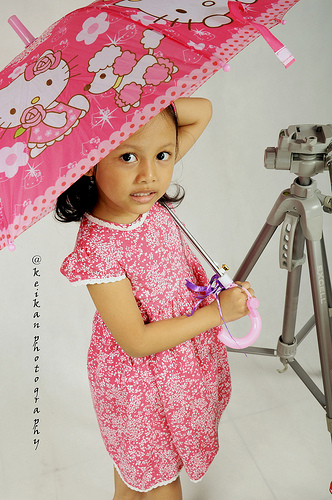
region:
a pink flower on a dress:
[125, 424, 134, 434]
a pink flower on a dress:
[179, 424, 185, 429]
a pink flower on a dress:
[144, 467, 150, 474]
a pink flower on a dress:
[131, 449, 140, 457]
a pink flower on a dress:
[147, 430, 153, 439]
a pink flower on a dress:
[115, 431, 124, 440]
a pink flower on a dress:
[145, 408, 153, 417]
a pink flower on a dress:
[128, 453, 135, 459]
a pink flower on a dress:
[195, 403, 202, 411]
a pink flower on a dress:
[190, 467, 197, 471]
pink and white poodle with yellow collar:
[78, 29, 188, 112]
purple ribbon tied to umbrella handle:
[181, 268, 234, 308]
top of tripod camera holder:
[262, 114, 330, 188]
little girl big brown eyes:
[116, 140, 177, 169]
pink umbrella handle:
[216, 294, 263, 350]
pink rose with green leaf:
[11, 101, 50, 136]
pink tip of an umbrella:
[4, 11, 35, 46]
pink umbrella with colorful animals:
[2, 15, 187, 96]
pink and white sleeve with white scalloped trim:
[56, 255, 131, 286]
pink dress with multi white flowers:
[159, 358, 215, 435]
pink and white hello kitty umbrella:
[0, 0, 298, 249]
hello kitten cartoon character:
[0, 46, 87, 154]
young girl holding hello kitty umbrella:
[0, 0, 298, 498]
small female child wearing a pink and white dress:
[56, 205, 227, 488]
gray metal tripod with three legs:
[221, 118, 326, 429]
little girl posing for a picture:
[2, 0, 292, 492]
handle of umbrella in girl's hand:
[213, 262, 258, 345]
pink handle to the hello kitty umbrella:
[213, 283, 257, 344]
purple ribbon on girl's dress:
[185, 272, 236, 341]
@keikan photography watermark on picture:
[29, 252, 43, 452]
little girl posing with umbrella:
[2, 2, 331, 497]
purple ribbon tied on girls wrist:
[176, 271, 240, 323]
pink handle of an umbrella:
[204, 296, 274, 366]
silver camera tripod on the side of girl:
[225, 110, 330, 467]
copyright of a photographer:
[18, 252, 49, 462]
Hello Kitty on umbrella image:
[1, 46, 94, 159]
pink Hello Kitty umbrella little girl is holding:
[0, 3, 300, 240]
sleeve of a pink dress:
[60, 249, 130, 287]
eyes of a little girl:
[114, 144, 180, 169]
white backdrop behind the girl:
[224, 77, 330, 116]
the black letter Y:
[32, 436, 41, 452]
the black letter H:
[30, 424, 43, 436]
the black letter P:
[28, 415, 43, 429]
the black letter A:
[29, 405, 44, 416]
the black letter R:
[31, 393, 43, 406]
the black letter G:
[28, 385, 43, 398]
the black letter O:
[30, 373, 46, 383]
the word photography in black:
[30, 333, 44, 458]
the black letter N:
[29, 320, 43, 329]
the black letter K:
[30, 296, 43, 306]